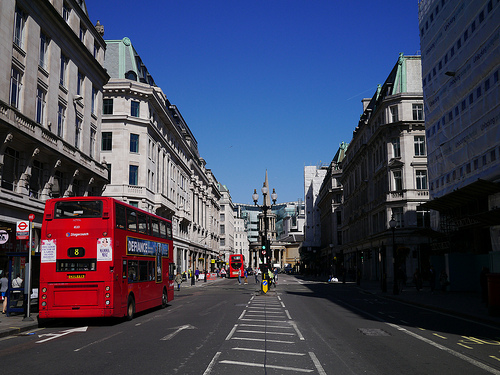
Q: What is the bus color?
A: Red.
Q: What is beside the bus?
A: Buildings.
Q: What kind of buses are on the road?
A: Double decker.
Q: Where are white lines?
A: On the road.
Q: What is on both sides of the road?
A: Buildings.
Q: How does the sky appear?
A: Bright blue.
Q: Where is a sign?
A: On side of the bus.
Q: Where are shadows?
A: On right side of the road.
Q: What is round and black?
A: Tires.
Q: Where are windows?
A: On the buildings.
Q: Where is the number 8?
A: On back of a bus.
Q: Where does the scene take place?
A: On a city street.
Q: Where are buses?
A: On the road.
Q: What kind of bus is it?
A: Double decker.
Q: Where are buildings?
A: On both sides of the road.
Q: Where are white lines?
A: On the road.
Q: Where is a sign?
A: On side of the bus.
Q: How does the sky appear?
A: Very blue.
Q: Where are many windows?
A: On the buildings.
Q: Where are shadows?
A: On the ground.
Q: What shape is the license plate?
A: Rectangular.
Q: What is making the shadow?
A: Buildings.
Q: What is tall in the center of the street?
A: Light post.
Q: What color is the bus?
A: Red.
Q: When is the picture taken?
A: Daytime.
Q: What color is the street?
A: Black.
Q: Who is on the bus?
A: Passengers.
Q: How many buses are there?
A: Two.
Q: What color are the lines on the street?
A: White.